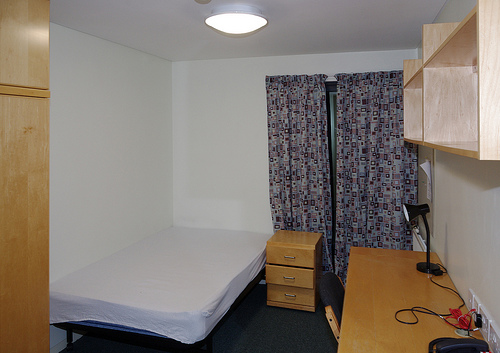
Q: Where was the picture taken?
A: It was taken at the bedroom.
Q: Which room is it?
A: It is a bedroom.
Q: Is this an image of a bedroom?
A: Yes, it is showing a bedroom.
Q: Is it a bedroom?
A: Yes, it is a bedroom.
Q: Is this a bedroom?
A: Yes, it is a bedroom.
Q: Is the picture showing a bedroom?
A: Yes, it is showing a bedroom.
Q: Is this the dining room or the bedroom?
A: It is the bedroom.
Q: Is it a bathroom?
A: No, it is a bedroom.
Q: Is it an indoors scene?
A: Yes, it is indoors.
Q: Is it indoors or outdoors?
A: It is indoors.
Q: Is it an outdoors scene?
A: No, it is indoors.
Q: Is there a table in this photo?
A: Yes, there is a table.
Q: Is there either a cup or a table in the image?
A: Yes, there is a table.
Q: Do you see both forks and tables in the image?
A: No, there is a table but no forks.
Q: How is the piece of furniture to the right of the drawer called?
A: The piece of furniture is a table.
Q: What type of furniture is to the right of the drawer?
A: The piece of furniture is a table.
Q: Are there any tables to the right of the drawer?
A: Yes, there is a table to the right of the drawer.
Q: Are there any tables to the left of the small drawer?
A: No, the table is to the right of the drawer.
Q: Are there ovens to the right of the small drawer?
A: No, there is a table to the right of the drawer.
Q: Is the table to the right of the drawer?
A: Yes, the table is to the right of the drawer.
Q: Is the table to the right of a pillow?
A: No, the table is to the right of the drawer.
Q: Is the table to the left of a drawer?
A: No, the table is to the right of a drawer.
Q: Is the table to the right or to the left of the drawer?
A: The table is to the right of the drawer.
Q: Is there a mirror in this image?
A: No, there are no mirrors.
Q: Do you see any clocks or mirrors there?
A: No, there are no mirrors or clocks.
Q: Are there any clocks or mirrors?
A: No, there are no mirrors or clocks.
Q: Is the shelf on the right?
A: Yes, the shelf is on the right of the image.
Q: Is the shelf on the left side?
A: No, the shelf is on the right of the image.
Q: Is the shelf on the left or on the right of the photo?
A: The shelf is on the right of the image.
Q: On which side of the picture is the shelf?
A: The shelf is on the right of the image.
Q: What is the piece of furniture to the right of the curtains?
A: The piece of furniture is a shelf.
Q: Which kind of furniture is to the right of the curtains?
A: The piece of furniture is a shelf.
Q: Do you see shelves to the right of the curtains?
A: Yes, there is a shelf to the right of the curtains.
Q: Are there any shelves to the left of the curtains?
A: No, the shelf is to the right of the curtains.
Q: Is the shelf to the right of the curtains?
A: Yes, the shelf is to the right of the curtains.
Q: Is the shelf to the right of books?
A: No, the shelf is to the right of the curtains.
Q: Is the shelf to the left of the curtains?
A: No, the shelf is to the right of the curtains.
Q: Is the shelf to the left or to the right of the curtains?
A: The shelf is to the right of the curtains.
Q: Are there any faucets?
A: No, there are no faucets.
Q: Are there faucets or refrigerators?
A: No, there are no faucets or refrigerators.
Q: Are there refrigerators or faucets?
A: No, there are no faucets or refrigerators.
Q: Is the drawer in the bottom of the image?
A: Yes, the drawer is in the bottom of the image.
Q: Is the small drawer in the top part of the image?
A: No, the drawer is in the bottom of the image.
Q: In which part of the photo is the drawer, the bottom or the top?
A: The drawer is in the bottom of the image.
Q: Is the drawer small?
A: Yes, the drawer is small.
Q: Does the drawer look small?
A: Yes, the drawer is small.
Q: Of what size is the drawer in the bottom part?
A: The drawer is small.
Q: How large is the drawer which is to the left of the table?
A: The drawer is small.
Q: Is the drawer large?
A: No, the drawer is small.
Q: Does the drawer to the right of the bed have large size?
A: No, the drawer is small.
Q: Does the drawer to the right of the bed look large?
A: No, the drawer is small.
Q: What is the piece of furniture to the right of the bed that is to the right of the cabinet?
A: The piece of furniture is a drawer.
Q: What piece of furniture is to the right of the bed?
A: The piece of furniture is a drawer.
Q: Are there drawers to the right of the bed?
A: Yes, there is a drawer to the right of the bed.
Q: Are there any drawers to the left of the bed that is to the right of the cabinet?
A: No, the drawer is to the right of the bed.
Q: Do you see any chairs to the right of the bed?
A: No, there is a drawer to the right of the bed.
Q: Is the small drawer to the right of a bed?
A: Yes, the drawer is to the right of a bed.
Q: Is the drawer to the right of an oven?
A: No, the drawer is to the right of a bed.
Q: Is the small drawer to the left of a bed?
A: No, the drawer is to the right of a bed.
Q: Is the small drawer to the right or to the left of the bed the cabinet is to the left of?
A: The drawer is to the right of the bed.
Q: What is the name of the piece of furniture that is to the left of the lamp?
A: The piece of furniture is a drawer.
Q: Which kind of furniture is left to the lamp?
A: The piece of furniture is a drawer.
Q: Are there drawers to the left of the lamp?
A: Yes, there is a drawer to the left of the lamp.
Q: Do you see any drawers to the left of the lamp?
A: Yes, there is a drawer to the left of the lamp.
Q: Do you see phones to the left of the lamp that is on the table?
A: No, there is a drawer to the left of the lamp.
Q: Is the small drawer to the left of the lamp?
A: Yes, the drawer is to the left of the lamp.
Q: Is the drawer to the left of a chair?
A: No, the drawer is to the left of the lamp.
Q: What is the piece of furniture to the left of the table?
A: The piece of furniture is a drawer.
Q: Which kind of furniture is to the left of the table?
A: The piece of furniture is a drawer.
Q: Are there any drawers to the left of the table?
A: Yes, there is a drawer to the left of the table.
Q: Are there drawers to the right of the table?
A: No, the drawer is to the left of the table.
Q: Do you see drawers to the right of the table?
A: No, the drawer is to the left of the table.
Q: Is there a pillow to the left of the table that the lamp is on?
A: No, there is a drawer to the left of the table.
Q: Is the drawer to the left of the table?
A: Yes, the drawer is to the left of the table.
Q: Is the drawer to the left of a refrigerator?
A: No, the drawer is to the left of the table.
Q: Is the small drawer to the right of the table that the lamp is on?
A: No, the drawer is to the left of the table.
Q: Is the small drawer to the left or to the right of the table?
A: The drawer is to the left of the table.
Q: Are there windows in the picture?
A: Yes, there is a window.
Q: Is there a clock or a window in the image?
A: Yes, there is a window.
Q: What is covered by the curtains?
A: The window is covered by the curtains.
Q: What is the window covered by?
A: The window is covered by the curtains.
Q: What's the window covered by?
A: The window is covered by the curtains.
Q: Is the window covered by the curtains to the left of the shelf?
A: Yes, the window is covered by the curtains.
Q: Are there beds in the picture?
A: Yes, there is a bed.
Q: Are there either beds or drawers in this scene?
A: Yes, there is a bed.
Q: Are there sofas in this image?
A: No, there are no sofas.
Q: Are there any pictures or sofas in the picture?
A: No, there are no sofas or pictures.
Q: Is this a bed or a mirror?
A: This is a bed.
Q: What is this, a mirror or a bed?
A: This is a bed.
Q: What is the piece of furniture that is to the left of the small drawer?
A: The piece of furniture is a bed.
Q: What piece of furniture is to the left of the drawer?
A: The piece of furniture is a bed.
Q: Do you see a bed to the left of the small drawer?
A: Yes, there is a bed to the left of the drawer.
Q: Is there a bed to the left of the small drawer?
A: Yes, there is a bed to the left of the drawer.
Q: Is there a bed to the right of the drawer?
A: No, the bed is to the left of the drawer.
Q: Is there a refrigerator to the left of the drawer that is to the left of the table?
A: No, there is a bed to the left of the drawer.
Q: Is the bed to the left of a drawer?
A: Yes, the bed is to the left of a drawer.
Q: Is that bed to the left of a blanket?
A: No, the bed is to the left of a drawer.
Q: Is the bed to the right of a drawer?
A: No, the bed is to the left of a drawer.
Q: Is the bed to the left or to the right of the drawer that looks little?
A: The bed is to the left of the drawer.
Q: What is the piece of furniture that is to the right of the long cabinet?
A: The piece of furniture is a bed.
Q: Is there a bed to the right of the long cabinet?
A: Yes, there is a bed to the right of the cabinet.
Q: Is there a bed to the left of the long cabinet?
A: No, the bed is to the right of the cabinet.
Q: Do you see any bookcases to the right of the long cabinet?
A: No, there is a bed to the right of the cabinet.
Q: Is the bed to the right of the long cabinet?
A: Yes, the bed is to the right of the cabinet.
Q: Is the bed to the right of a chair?
A: No, the bed is to the right of the cabinet.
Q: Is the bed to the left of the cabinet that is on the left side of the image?
A: No, the bed is to the right of the cabinet.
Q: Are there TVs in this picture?
A: No, there are no tvs.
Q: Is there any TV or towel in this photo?
A: No, there are no televisions or towels.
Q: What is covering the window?
A: The curtains are covering the window.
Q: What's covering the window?
A: The curtains are covering the window.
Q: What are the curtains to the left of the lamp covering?
A: The curtains are covering the window.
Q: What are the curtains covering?
A: The curtains are covering the window.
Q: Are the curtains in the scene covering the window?
A: Yes, the curtains are covering the window.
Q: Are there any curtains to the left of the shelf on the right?
A: Yes, there are curtains to the left of the shelf.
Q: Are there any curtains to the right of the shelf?
A: No, the curtains are to the left of the shelf.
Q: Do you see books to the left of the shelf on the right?
A: No, there are curtains to the left of the shelf.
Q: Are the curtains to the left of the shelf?
A: Yes, the curtains are to the left of the shelf.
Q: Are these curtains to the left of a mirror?
A: No, the curtains are to the left of the shelf.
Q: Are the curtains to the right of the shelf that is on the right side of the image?
A: No, the curtains are to the left of the shelf.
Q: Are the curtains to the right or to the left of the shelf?
A: The curtains are to the left of the shelf.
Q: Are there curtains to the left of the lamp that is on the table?
A: Yes, there are curtains to the left of the lamp.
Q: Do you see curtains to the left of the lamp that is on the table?
A: Yes, there are curtains to the left of the lamp.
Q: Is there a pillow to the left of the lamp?
A: No, there are curtains to the left of the lamp.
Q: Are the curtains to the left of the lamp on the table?
A: Yes, the curtains are to the left of the lamp.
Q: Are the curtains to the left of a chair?
A: No, the curtains are to the left of the lamp.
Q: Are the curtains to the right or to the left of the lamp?
A: The curtains are to the left of the lamp.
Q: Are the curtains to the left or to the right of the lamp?
A: The curtains are to the left of the lamp.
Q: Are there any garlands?
A: No, there are no garlands.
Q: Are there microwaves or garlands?
A: No, there are no garlands or microwaves.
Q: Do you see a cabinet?
A: Yes, there is a cabinet.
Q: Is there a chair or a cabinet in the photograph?
A: Yes, there is a cabinet.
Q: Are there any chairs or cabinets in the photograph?
A: Yes, there is a cabinet.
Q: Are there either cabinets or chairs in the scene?
A: Yes, there is a cabinet.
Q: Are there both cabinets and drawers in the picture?
A: Yes, there are both a cabinet and a drawer.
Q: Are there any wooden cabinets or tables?
A: Yes, there is a wood cabinet.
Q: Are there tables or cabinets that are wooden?
A: Yes, the cabinet is wooden.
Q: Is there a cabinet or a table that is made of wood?
A: Yes, the cabinet is made of wood.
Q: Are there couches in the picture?
A: No, there are no couches.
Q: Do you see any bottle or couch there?
A: No, there are no couches or bottles.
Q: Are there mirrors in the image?
A: No, there are no mirrors.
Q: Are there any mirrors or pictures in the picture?
A: No, there are no mirrors or pictures.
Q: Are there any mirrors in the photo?
A: No, there are no mirrors.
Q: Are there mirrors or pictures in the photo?
A: No, there are no mirrors or pictures.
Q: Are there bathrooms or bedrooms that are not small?
A: No, there is a bedroom but it is small.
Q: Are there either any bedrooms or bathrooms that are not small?
A: No, there is a bedroom but it is small.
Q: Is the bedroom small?
A: Yes, the bedroom is small.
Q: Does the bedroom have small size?
A: Yes, the bedroom is small.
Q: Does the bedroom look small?
A: Yes, the bedroom is small.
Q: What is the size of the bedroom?
A: The bedroom is small.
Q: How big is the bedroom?
A: The bedroom is small.